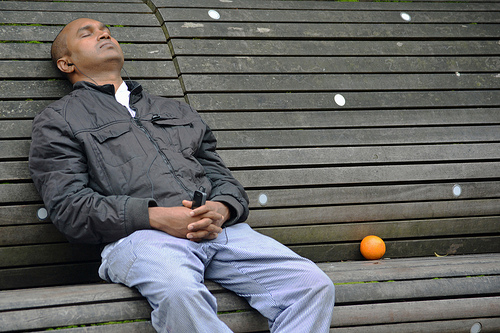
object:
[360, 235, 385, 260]
orange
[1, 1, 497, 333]
bench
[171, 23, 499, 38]
slat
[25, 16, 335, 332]
man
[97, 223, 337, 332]
jeans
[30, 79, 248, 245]
jacket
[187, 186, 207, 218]
mp3 player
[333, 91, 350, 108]
dot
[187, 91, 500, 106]
slat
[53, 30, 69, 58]
hair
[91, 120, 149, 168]
pocket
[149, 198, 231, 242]
skin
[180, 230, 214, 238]
fingers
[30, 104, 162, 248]
sleeve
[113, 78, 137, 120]
shirt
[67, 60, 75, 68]
earbud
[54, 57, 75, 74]
ear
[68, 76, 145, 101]
collar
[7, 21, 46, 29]
vegetation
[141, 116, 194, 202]
zipper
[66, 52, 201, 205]
wire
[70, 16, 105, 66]
skin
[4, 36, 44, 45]
moss